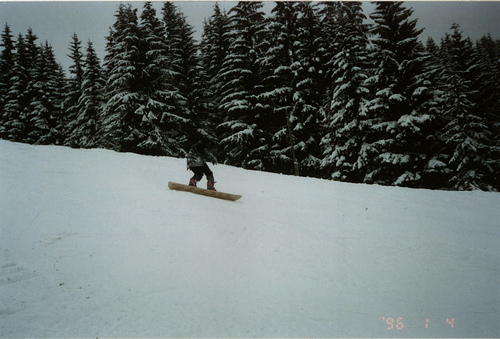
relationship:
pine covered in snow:
[0, 0, 500, 191] [3, 142, 499, 337]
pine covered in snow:
[0, 0, 500, 191] [229, 4, 326, 168]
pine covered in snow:
[0, 0, 500, 191] [103, 21, 191, 151]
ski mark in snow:
[136, 210, 331, 268] [3, 142, 499, 337]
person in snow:
[186, 139, 219, 190] [3, 142, 499, 337]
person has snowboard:
[186, 139, 219, 190] [170, 182, 241, 201]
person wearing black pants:
[186, 139, 219, 190] [190, 164, 216, 182]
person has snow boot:
[186, 139, 219, 190] [205, 176, 215, 191]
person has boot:
[186, 139, 219, 190] [189, 178, 197, 187]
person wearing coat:
[186, 139, 219, 190] [187, 143, 213, 169]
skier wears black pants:
[163, 132, 248, 202] [186, 159, 217, 182]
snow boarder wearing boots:
[173, 131, 220, 193] [181, 173, 230, 191]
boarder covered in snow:
[173, 127, 223, 190] [268, 210, 440, 323]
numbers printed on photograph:
[353, 292, 488, 337] [385, 301, 475, 336]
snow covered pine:
[3, 0, 500, 338] [0, 0, 500, 191]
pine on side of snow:
[0, 0, 500, 191] [8, 142, 498, 227]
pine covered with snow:
[0, 0, 500, 191] [399, 112, 428, 124]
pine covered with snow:
[8, 33, 35, 138] [399, 112, 428, 124]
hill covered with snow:
[5, 108, 357, 304] [150, 265, 265, 329]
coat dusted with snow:
[186, 144, 212, 167] [3, 142, 499, 337]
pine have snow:
[0, 0, 500, 191] [402, 114, 412, 121]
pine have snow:
[0, 0, 500, 191] [231, 98, 239, 103]